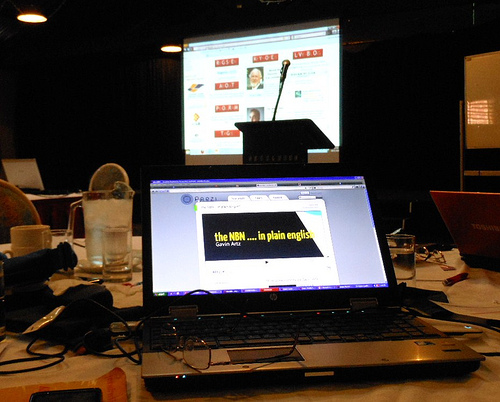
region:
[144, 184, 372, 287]
a laptop screen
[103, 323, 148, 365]
black chord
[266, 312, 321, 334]
keys on the laptop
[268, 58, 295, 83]
a microphone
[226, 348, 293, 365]
pad on the laptop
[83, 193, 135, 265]
a clear glass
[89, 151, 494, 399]
this is a laptop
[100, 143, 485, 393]
the laptop is open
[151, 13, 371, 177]
this is a projection screen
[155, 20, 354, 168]
image on the screen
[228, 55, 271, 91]
man on the screen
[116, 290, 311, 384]
a pair of eyeglasses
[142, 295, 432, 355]
laptop keyboard is black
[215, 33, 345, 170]
this is a podium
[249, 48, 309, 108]
this is a microphone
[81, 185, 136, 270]
A glass of ice water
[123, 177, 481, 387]
An open black laptop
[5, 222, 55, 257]
A yellow coffee mug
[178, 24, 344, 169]
A large computer monitor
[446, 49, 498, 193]
A board in a classroom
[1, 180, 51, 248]
A chair sitting at a table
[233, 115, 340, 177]
A podium at the front of a classroom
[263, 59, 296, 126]
A microphone on a podium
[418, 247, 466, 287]
A white piece of paper on a table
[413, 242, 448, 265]
A pair of eyeglasses on a piece of paper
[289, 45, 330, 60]
red symbol on the overhead screen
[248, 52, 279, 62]
red symbol on the overhead screen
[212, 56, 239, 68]
red symbol on the overhead screen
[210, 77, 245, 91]
red symbol on the overhead screen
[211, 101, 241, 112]
red symbol on the overhead screen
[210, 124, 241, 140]
red symbol on the overhead screen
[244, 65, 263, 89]
head on the overhead screen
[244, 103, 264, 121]
head on the overhead screen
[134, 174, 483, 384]
laptop on the table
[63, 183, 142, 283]
water pitcher on the table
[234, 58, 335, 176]
a podium and microphone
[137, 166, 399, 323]
a computer monitor for the overhead screen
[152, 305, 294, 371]
a pair of eye glasses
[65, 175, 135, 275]
a glass pitcher of water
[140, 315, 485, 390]
a grey laptop computer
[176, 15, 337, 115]
an overhead A/V screen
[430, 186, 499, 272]
a red laptop computer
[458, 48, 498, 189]
a whiteboard screen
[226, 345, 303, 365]
the laptops scrolling pad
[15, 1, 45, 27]
a ceiling hanging lamp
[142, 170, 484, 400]
laptop is gray and black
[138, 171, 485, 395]
laptop is turned on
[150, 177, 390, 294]
laptop screen is on a webpage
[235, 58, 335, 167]
podium has a metal microphone